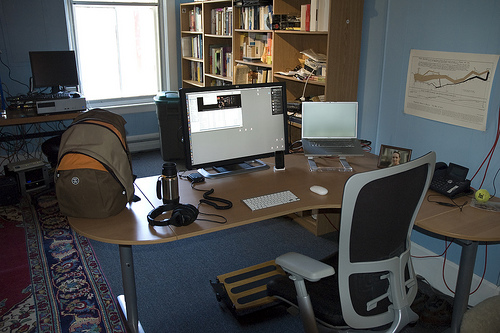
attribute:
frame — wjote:
[63, 1, 192, 123]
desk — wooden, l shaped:
[79, 133, 496, 329]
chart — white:
[400, 36, 499, 136]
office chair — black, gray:
[273, 159, 431, 333]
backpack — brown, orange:
[51, 110, 133, 222]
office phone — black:
[433, 159, 469, 206]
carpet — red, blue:
[5, 209, 75, 331]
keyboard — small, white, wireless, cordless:
[241, 189, 301, 214]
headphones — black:
[148, 196, 203, 228]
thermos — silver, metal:
[156, 168, 180, 203]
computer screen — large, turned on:
[177, 84, 288, 165]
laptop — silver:
[302, 102, 366, 162]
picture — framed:
[375, 142, 409, 168]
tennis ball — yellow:
[475, 183, 492, 204]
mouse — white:
[308, 177, 329, 200]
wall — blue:
[382, 2, 498, 182]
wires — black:
[189, 181, 235, 222]